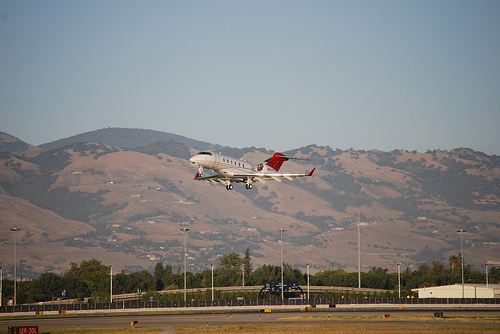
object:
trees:
[0, 247, 500, 306]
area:
[3, 285, 492, 332]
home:
[410, 284, 493, 298]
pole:
[356, 208, 361, 290]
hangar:
[410, 283, 494, 299]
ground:
[0, 305, 500, 334]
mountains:
[0, 128, 500, 283]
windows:
[223, 158, 244, 167]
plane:
[190, 151, 316, 190]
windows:
[197, 152, 211, 156]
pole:
[13, 230, 17, 304]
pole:
[111, 266, 113, 309]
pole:
[306, 265, 309, 303]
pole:
[399, 264, 402, 303]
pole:
[485, 265, 489, 296]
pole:
[242, 265, 245, 287]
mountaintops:
[0, 127, 500, 161]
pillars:
[357, 212, 360, 287]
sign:
[259, 267, 310, 299]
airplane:
[189, 151, 316, 190]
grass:
[4, 314, 500, 334]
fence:
[0, 298, 498, 313]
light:
[9, 226, 21, 231]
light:
[210, 264, 213, 266]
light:
[277, 230, 287, 232]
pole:
[15, 232, 17, 305]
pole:
[184, 233, 187, 308]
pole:
[211, 266, 214, 302]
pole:
[280, 229, 283, 303]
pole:
[461, 230, 465, 303]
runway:
[0, 311, 499, 328]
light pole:
[281, 229, 284, 304]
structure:
[412, 284, 493, 298]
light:
[457, 229, 467, 232]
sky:
[0, 0, 500, 156]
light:
[180, 227, 189, 232]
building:
[409, 284, 495, 299]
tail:
[264, 152, 290, 173]